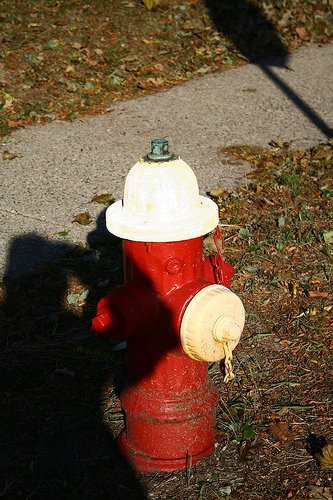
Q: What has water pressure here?
A: Hydrant.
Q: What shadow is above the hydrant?
A: Sign shadow.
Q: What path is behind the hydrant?
A: Sidewalk.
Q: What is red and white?
A: The fire hdrant.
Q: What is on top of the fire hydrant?
A: White top.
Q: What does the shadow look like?
A: Black and on the ground.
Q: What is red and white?
A: The fire hydrant.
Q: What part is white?
A: The top part.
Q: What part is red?
A: The body of the fire hydrant.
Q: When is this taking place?
A: Daytime.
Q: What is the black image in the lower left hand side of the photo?
A: Shadow.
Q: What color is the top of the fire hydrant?
A: White.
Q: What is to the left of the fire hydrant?
A: Sidewalk.